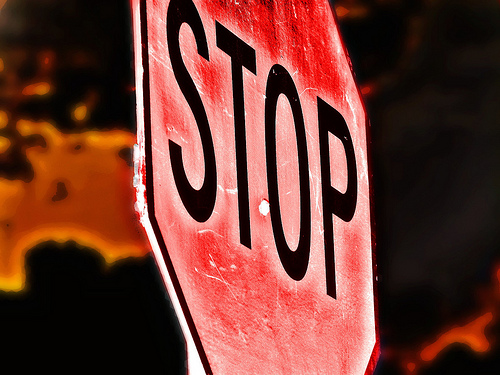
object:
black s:
[167, 0, 218, 223]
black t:
[215, 19, 257, 251]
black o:
[265, 63, 311, 281]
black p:
[316, 96, 358, 300]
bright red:
[272, 7, 319, 29]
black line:
[141, 0, 382, 374]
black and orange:
[158, 163, 219, 218]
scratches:
[308, 162, 324, 232]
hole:
[258, 199, 270, 216]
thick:
[215, 20, 258, 76]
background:
[1, 1, 499, 374]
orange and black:
[38, 188, 125, 279]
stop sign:
[167, 0, 358, 300]